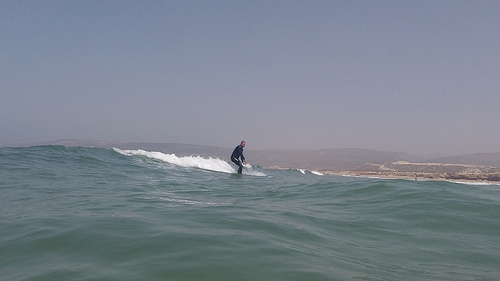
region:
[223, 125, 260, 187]
man in a wetsuit surfing a small wave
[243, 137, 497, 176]
a mountain range in hazy weather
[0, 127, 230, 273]
a small wave in the ocean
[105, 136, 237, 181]
a whitecap on a wave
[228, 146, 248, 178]
a black wetsuit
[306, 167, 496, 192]
shoreline at the ocean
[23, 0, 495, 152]
a cloudless sky with some haze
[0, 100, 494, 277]
the ocean on a calm day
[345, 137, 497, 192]
paths up into the mountains, along the coast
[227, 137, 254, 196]
a surfer with short hair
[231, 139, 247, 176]
a surfer in the water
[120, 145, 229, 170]
white waves behind the surfer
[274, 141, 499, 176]
mountains in the distance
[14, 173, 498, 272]
the blue-green waters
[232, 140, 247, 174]
surfer wearing a wet suit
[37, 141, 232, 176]
a small wave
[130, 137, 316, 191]
surfer riding a small wave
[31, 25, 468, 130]
a sky with no clouds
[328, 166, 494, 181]
land in the background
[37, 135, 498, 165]
the mountain tops in the distance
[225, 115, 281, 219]
the man is surfing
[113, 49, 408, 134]
the sky is clear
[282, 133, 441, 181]
hills in the distance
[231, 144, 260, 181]
the man is wearing wet suit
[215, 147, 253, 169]
the wet suit is blue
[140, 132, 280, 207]
the splashes are white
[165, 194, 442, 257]
the water is blue green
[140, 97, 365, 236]
the man is surfing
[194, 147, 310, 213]
the man on the water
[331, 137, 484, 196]
the shore is brown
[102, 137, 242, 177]
a white cap of a wave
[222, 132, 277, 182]
a man surfing in the ocean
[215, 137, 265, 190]
a man wearing a blue and black wet suit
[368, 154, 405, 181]
a sandy road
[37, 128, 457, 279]
wavy ocean water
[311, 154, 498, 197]
a long strip of sandy beach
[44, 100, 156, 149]
a foggy grey landscape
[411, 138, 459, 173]
a hill in the distance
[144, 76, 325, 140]
a grey sky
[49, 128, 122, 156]
bluffs by the ocean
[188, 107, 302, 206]
the man is surfing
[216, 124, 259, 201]
the man on the water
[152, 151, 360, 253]
the water is green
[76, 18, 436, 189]
the sky is clear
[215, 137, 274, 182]
the man is wearing wet suit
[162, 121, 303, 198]
the splash on the water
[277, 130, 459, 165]
mountains in the distance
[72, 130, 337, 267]
the water is wavy